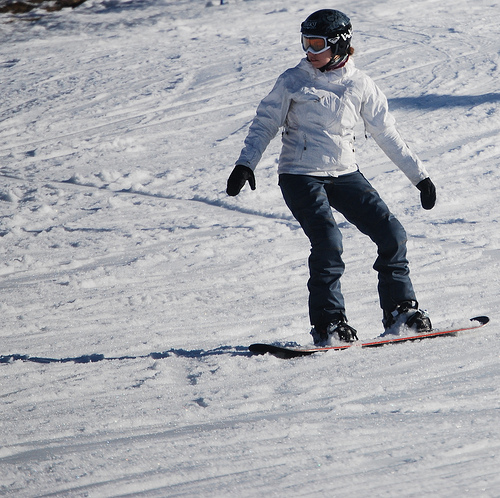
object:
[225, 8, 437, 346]
person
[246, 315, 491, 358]
snowboard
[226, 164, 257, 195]
gloves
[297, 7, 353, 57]
helmet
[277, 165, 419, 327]
pants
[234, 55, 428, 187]
jacket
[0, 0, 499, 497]
snow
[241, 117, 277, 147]
elbow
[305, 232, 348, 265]
knee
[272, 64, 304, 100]
shoulder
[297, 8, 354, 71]
head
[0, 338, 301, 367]
shadow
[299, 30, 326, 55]
goggles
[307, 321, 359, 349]
boots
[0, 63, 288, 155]
tracks